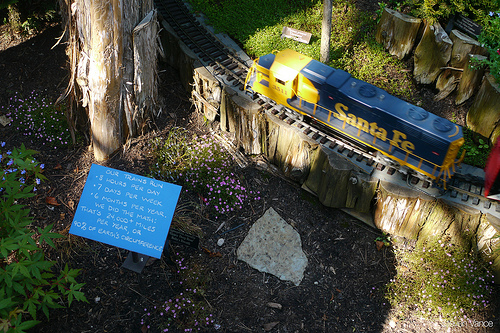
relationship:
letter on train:
[329, 99, 419, 156] [243, 41, 467, 178]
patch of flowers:
[382, 225, 497, 323] [382, 232, 497, 304]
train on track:
[244, 47, 463, 192] [150, 0, 497, 216]